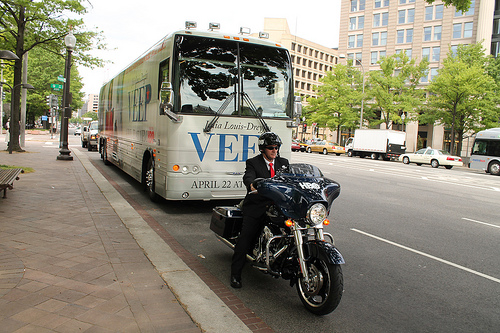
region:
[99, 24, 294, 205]
white bus behind motorcycle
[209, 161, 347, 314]
black motorcycle in front of bus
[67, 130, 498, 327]
black asphalt street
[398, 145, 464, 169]
white vehicle on street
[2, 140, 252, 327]
sidewalk next to street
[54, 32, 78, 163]
lamp post on sidewalk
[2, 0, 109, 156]
large tree on sidewalk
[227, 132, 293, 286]
man sitting on motorcycle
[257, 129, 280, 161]
black helmet on man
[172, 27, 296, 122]
glass windshield on bus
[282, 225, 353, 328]
black tire on the bike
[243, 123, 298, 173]
helmet on the man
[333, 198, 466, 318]
white line on the road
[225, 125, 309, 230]
man with a red tie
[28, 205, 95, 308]
sidewalk next to the road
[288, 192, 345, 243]
light on the bike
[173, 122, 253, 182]
blue letters on the bus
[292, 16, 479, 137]
green trees nxt to the street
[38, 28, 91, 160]
light on the sidewalk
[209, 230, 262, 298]
leg of the man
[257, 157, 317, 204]
red necktie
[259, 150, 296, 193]
red necktie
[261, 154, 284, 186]
red necktie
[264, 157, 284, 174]
red necktie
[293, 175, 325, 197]
Business logo on motorcycle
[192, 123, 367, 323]
Man in suit riding a motorcycle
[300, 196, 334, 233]
Headlight of a motorcycle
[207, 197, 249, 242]
Luggage accessory on a motorcycle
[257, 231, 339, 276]
Engine guard on a motorcycle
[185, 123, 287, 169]
Company name on the front of passenger bus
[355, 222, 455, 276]
White lines painted on the street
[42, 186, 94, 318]
Sidewalk made with square tiles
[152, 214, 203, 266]
Street gutter made from bricks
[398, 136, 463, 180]
Cab parked on the street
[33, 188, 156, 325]
paved sidewalk by a road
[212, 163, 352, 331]
Motorcycle on a road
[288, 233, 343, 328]
Wheel on a motorcycle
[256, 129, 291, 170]
Helmet on a man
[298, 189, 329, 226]
Light on a motorcycle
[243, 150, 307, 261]
Suit on a man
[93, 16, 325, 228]
Blue and white bus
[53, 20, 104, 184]
Light post by a road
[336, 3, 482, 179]
Building by a road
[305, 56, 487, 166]
Green trees by a road